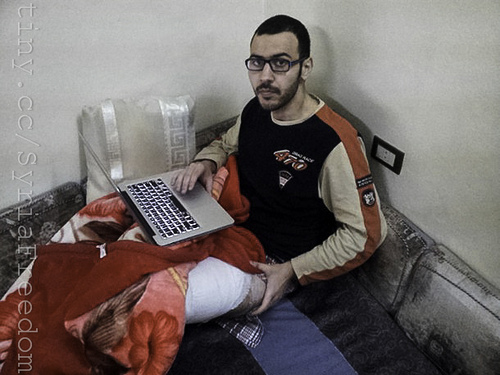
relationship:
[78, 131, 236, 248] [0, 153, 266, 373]
laptop on bedspread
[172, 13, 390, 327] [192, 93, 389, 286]
man wearing shirt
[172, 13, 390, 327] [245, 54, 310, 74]
man wearing glasses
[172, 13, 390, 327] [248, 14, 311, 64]
man has hair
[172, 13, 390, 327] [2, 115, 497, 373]
man sitting on bed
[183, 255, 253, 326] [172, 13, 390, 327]
bandage on man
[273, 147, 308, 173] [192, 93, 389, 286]
logo on shirt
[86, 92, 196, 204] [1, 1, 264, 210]
cushion against wall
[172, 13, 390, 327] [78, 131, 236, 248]
man holding laptop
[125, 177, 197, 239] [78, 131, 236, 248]
keyboard on laptop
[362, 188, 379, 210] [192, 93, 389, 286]
patch on shirt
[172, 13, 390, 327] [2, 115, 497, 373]
man on bed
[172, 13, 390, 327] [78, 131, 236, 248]
man using laptop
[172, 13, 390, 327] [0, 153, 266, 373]
man with bedspread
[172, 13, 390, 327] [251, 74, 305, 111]
man with beard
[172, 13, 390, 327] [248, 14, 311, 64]
man with hair